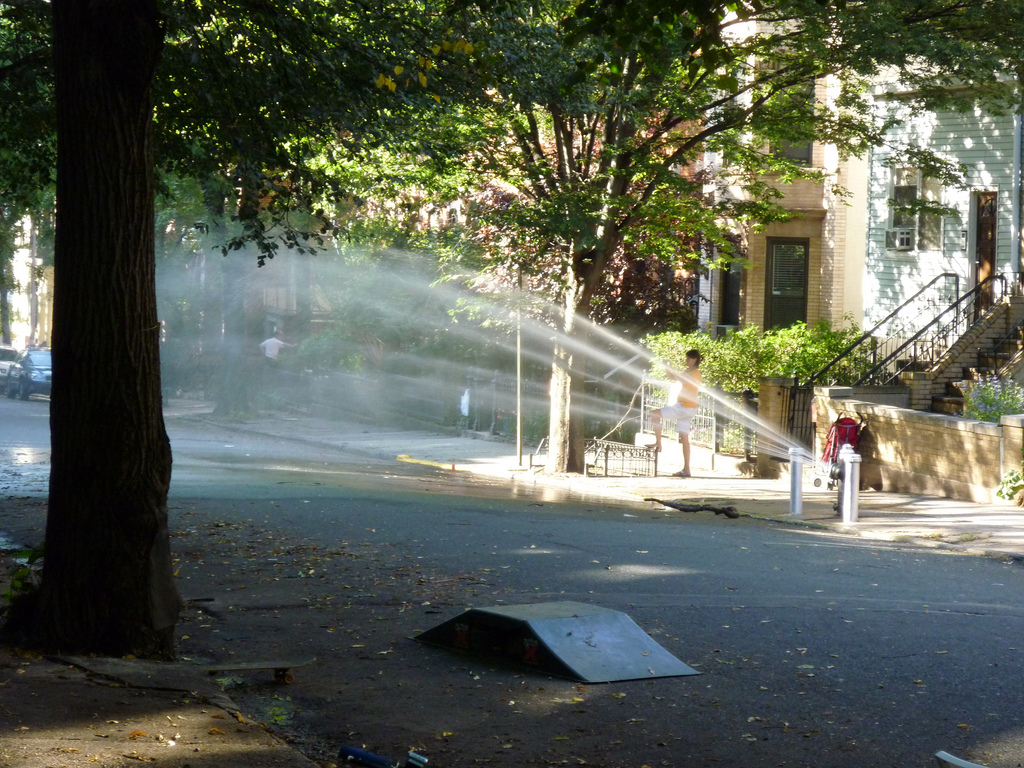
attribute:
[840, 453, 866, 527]
post — white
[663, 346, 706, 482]
person — standing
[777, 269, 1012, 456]
stairs — leading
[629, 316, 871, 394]
shrubbery — green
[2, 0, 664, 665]
tree — large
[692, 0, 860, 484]
building — white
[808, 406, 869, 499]
carriage — red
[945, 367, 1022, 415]
flowers — blue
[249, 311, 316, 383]
shirt — white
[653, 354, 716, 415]
shirt — yellow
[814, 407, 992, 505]
wall — brick